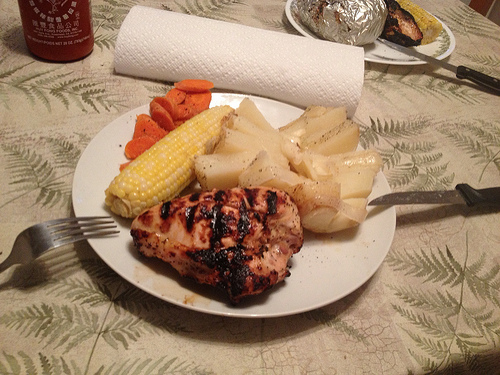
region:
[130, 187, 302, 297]
a grilled piece of chicken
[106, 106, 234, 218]
corn on the cob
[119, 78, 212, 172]
slice carrots with pepper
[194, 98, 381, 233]
sliced up baked potato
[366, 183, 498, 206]
a steak knife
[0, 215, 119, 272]
a silver fork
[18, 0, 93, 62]
bottle of hot sauce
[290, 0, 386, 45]
baked potato wrapped in foil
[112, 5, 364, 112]
white paper towel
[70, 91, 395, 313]
a plate full of food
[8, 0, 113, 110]
Siracha bottle on a table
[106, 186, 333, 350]
Grilled chicken breast on a plate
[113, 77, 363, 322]
Grilled chicken and vegetables dinner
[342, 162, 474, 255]
Knife on a plate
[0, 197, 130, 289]
Fork on a plate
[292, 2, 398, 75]
Baked potato on a plate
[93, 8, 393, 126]
Roll of paper towels on table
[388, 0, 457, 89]
Corn on the cob and chicken on a plate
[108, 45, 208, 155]
Carrots on a plate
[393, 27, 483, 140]
Knife leaning on a plate on a table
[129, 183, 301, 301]
A piece of chicken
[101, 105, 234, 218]
an ear of corn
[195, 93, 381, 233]
many slices of roasted potatoes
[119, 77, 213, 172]
a small portion of carrots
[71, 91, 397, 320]
a white plate holding a meal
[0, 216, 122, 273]
an stainless steel fork resting on a plate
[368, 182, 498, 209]
an stainless steel knife resting on a plate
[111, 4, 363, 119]
a roll of paper towels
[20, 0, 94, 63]
A bottle of sriracha hot sauce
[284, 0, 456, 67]
a white plate holding a meal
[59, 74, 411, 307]
chicken and vegetables on white plate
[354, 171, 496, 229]
sharp knife is resting on side of plate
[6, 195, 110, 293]
fork is resting on side of plate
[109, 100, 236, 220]
corn on the cob is touching the chicken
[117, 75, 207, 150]
small serving of sliced carrots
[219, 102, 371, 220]
sliced cooked potato wedges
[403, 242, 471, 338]
table cloth with green fern design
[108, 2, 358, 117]
white paper towel for napkin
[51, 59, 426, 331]
white plate is round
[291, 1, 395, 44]
object cooked in tinfoil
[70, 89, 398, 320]
Plate is round and white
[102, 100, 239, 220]
Corn on round white plate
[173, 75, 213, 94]
Orange carrot next to corn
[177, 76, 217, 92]
Orange carrot next to another carrot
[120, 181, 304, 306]
Chicken next to corn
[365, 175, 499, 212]
Knife blade on plate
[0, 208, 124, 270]
Fork on plate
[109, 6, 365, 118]
White paper roll behind plate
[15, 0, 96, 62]
Sriracha bottle by white paper roll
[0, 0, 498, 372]
Tablecloth has leaf prints